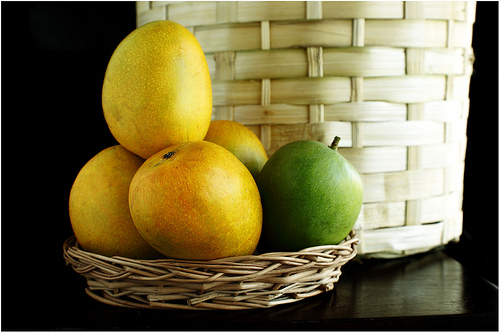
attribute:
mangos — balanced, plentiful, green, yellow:
[66, 20, 366, 261]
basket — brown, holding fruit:
[62, 231, 360, 311]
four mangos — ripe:
[66, 19, 270, 259]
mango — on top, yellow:
[99, 19, 214, 159]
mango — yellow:
[127, 139, 264, 262]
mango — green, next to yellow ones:
[259, 136, 365, 251]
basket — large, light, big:
[134, 3, 477, 258]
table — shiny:
[4, 219, 497, 326]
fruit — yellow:
[67, 142, 151, 260]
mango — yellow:
[205, 118, 269, 182]